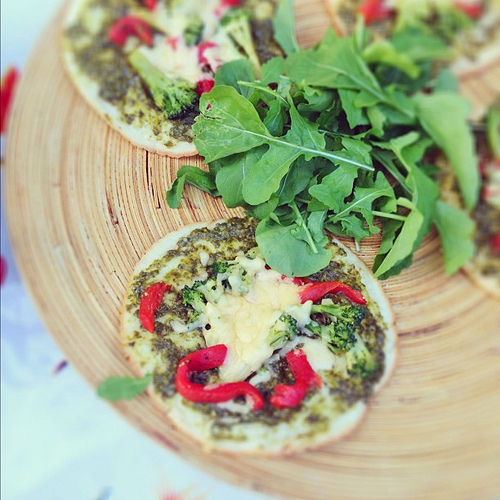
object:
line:
[41, 82, 117, 341]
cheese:
[202, 265, 302, 382]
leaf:
[93, 371, 150, 400]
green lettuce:
[280, 42, 414, 120]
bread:
[118, 217, 397, 455]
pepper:
[299, 278, 362, 304]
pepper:
[270, 348, 322, 411]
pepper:
[174, 345, 261, 407]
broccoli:
[342, 332, 380, 382]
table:
[0, 0, 283, 499]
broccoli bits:
[329, 298, 366, 328]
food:
[135, 280, 166, 333]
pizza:
[59, 0, 292, 159]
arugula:
[409, 88, 482, 216]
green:
[266, 227, 290, 259]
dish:
[0, 0, 499, 498]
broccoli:
[281, 299, 361, 356]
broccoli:
[177, 253, 259, 318]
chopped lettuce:
[163, 0, 499, 280]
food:
[180, 15, 207, 48]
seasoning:
[127, 217, 388, 442]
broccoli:
[127, 49, 198, 116]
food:
[211, 5, 261, 80]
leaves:
[191, 81, 375, 207]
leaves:
[251, 211, 334, 277]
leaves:
[165, 162, 219, 208]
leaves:
[321, 171, 396, 231]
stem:
[230, 128, 380, 175]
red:
[298, 364, 314, 386]